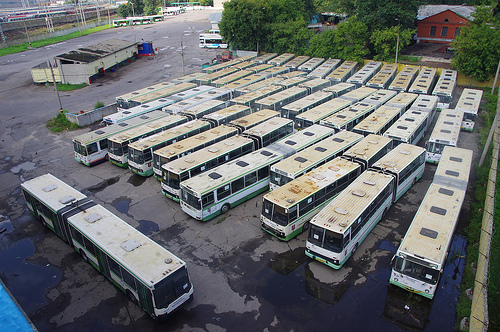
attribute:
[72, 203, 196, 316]
bus — white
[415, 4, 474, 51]
house — red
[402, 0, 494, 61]
building — white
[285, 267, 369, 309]
ground — wet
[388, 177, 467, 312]
bus — parked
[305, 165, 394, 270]
bus — parked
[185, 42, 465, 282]
picture — during the day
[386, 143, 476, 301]
busses — in a row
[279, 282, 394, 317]
puddle — large, water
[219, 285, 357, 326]
water — puddle, big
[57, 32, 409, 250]
buses — various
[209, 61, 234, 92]
buses — side by side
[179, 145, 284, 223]
bus — white, green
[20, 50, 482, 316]
busses — not moving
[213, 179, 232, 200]
windows — side windows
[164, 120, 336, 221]
bus — green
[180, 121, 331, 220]
bus — parked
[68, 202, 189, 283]
top — white